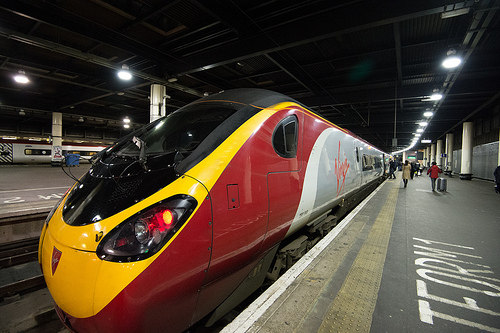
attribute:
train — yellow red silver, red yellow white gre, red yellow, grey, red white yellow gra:
[37, 86, 395, 332]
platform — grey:
[220, 169, 499, 332]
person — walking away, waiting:
[426, 157, 442, 196]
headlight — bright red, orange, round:
[96, 192, 196, 260]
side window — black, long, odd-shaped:
[272, 112, 299, 159]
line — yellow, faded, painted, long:
[317, 169, 404, 330]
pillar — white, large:
[460, 121, 474, 182]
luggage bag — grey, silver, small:
[437, 175, 448, 194]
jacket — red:
[427, 164, 443, 180]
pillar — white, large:
[443, 131, 455, 176]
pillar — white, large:
[435, 136, 443, 171]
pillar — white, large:
[429, 142, 437, 170]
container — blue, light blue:
[64, 151, 81, 166]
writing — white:
[412, 235, 499, 332]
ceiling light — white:
[442, 56, 464, 70]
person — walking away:
[399, 159, 413, 189]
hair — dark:
[403, 159, 411, 166]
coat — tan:
[403, 162, 413, 181]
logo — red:
[49, 245, 62, 275]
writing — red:
[331, 139, 352, 197]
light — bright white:
[429, 90, 441, 104]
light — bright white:
[422, 110, 433, 121]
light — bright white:
[418, 120, 429, 130]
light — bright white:
[416, 127, 424, 136]